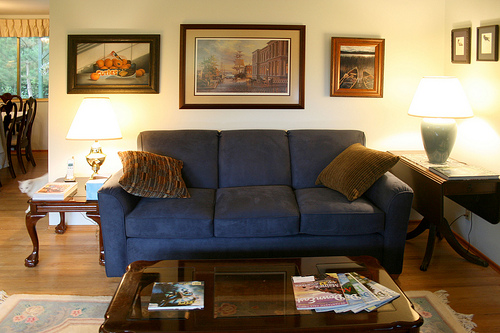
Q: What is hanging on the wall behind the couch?
A: Artwork.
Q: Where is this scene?
A: The living room.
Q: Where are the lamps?
A: On both sides of the couch.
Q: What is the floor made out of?
A: Wood.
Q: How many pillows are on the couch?
A: Two.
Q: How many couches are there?
A: One.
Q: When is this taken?
A: Daytime.